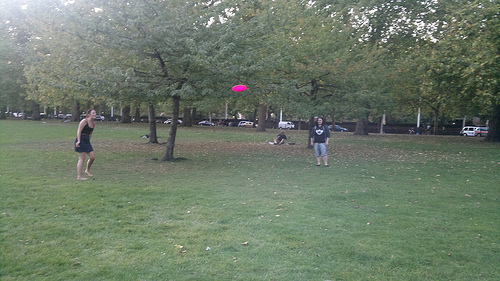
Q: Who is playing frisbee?
A: The ladies.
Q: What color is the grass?
A: Green.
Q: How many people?
A: Three.